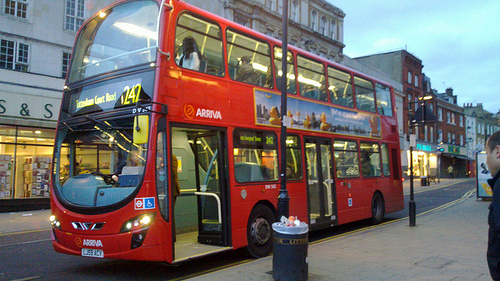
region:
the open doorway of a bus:
[167, 121, 244, 266]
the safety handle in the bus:
[194, 186, 224, 228]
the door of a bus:
[304, 136, 324, 225]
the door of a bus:
[317, 139, 335, 221]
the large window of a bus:
[52, 121, 157, 204]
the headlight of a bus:
[139, 213, 154, 228]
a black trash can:
[269, 220, 309, 276]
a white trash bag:
[272, 221, 306, 234]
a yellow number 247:
[120, 81, 145, 106]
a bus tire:
[246, 204, 276, 253]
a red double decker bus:
[50, 0, 405, 272]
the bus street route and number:
[69, 83, 155, 108]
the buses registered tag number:
[80, 246, 104, 258]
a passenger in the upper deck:
[176, 36, 203, 73]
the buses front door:
[168, 119, 228, 261]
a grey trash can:
[270, 215, 307, 280]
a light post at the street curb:
[278, 1, 289, 218]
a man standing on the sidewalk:
[486, 131, 498, 280]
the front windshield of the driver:
[51, 106, 163, 211]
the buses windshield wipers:
[61, 113, 136, 133]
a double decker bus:
[66, 0, 322, 267]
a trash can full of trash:
[264, 213, 319, 277]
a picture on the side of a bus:
[252, 84, 380, 137]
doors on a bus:
[301, 131, 343, 229]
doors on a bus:
[166, 119, 235, 264]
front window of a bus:
[52, 116, 153, 215]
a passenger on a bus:
[174, 25, 209, 74]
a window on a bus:
[223, 21, 278, 94]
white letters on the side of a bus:
[196, 100, 224, 120]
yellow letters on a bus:
[68, 79, 157, 111]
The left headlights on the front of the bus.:
[50, 214, 65, 226]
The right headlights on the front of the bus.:
[120, 215, 151, 230]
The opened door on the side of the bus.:
[166, 123, 236, 254]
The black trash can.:
[265, 215, 311, 277]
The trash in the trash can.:
[273, 214, 301, 226]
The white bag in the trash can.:
[272, 220, 309, 237]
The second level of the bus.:
[160, 7, 402, 137]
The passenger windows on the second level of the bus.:
[170, 30, 402, 112]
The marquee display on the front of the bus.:
[65, 87, 142, 112]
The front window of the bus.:
[56, 115, 147, 206]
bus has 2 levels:
[41, 0, 403, 277]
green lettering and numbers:
[62, 82, 163, 110]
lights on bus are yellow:
[30, 207, 192, 277]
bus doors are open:
[163, 104, 231, 265]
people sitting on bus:
[167, 26, 413, 117]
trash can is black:
[258, 200, 314, 278]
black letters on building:
[1, 82, 63, 142]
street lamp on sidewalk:
[398, 122, 438, 255]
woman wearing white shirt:
[173, 46, 207, 82]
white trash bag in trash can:
[249, 205, 321, 247]